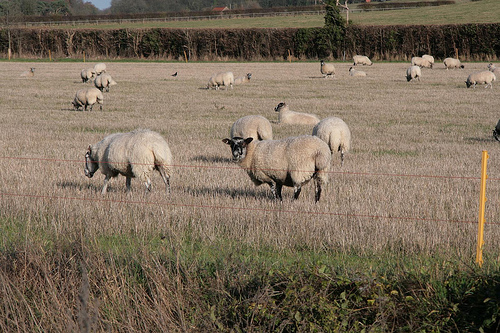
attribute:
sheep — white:
[463, 69, 496, 92]